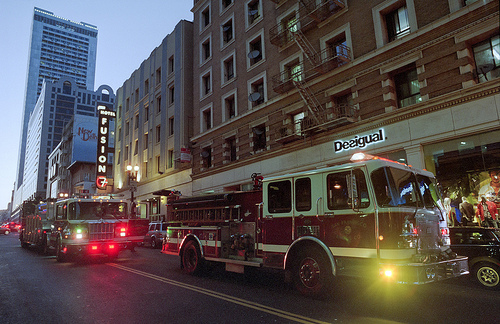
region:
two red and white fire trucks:
[14, 146, 471, 296]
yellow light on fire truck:
[368, 253, 408, 296]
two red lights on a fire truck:
[89, 238, 115, 258]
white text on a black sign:
[97, 111, 109, 181]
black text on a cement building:
[330, 125, 387, 155]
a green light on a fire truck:
[72, 224, 89, 235]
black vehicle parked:
[444, 220, 496, 289]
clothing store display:
[443, 188, 498, 223]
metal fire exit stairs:
[269, 1, 353, 150]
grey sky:
[98, 1, 182, 83]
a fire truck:
[160, 157, 472, 297]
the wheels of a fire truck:
[176, 230, 331, 297]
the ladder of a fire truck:
[163, 203, 241, 225]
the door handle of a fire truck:
[314, 194, 326, 221]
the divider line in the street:
[109, 260, 303, 320]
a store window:
[437, 168, 498, 223]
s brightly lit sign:
[93, 105, 117, 192]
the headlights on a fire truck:
[75, 220, 125, 265]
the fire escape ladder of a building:
[274, 77, 355, 134]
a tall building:
[21, 8, 99, 92]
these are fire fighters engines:
[20, 156, 442, 273]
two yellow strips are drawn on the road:
[138, 268, 270, 322]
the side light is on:
[381, 262, 400, 277]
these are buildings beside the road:
[42, 1, 497, 130]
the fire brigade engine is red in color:
[165, 170, 443, 272]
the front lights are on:
[65, 220, 137, 257]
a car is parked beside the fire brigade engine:
[455, 232, 499, 265]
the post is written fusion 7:
[92, 113, 114, 188]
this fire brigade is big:
[172, 165, 441, 266]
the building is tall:
[31, 15, 86, 80]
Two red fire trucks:
[13, 181, 471, 301]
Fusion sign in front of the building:
[94, 101, 109, 191]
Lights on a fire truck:
[19, 196, 134, 260]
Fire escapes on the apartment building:
[261, 0, 363, 133]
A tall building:
[14, 0, 101, 223]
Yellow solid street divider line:
[100, 256, 335, 321]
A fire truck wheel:
[171, 233, 211, 279]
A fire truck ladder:
[161, 205, 250, 227]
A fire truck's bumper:
[392, 251, 474, 283]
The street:
[0, 239, 365, 321]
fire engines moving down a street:
[22, 140, 477, 295]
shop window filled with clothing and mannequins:
[411, 122, 491, 232]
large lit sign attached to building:
[76, 90, 118, 195]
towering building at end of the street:
[5, 5, 121, 250]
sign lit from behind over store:
[306, 120, 391, 155]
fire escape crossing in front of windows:
[275, 10, 357, 145]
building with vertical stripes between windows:
[110, 15, 192, 202]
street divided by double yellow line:
[105, 256, 310, 312]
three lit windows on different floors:
[276, 10, 311, 140]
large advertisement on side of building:
[66, 96, 97, 179]